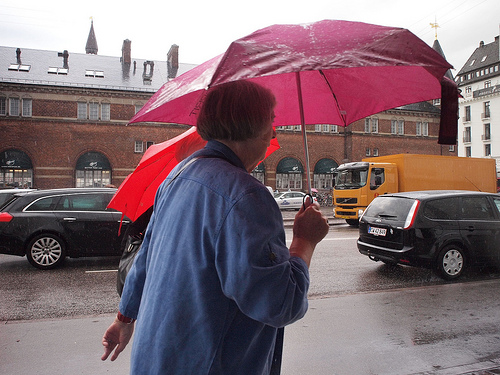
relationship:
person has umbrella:
[103, 78, 330, 374] [123, 20, 465, 127]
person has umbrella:
[115, 204, 155, 297] [104, 123, 281, 235]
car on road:
[0, 187, 144, 271] [1, 222, 497, 324]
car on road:
[357, 190, 499, 282] [1, 222, 497, 324]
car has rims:
[0, 187, 144, 271] [29, 235, 62, 266]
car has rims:
[357, 190, 499, 282] [442, 249, 465, 275]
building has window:
[454, 34, 499, 186] [465, 104, 471, 121]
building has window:
[454, 34, 499, 186] [482, 101, 490, 118]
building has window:
[454, 34, 499, 186] [482, 121, 490, 140]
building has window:
[454, 34, 499, 186] [463, 126, 473, 142]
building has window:
[454, 34, 499, 186] [465, 144, 472, 157]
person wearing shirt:
[103, 78, 330, 374] [116, 138, 310, 374]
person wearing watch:
[103, 78, 330, 374] [115, 310, 135, 326]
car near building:
[271, 188, 319, 210] [1, 44, 457, 196]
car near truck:
[357, 190, 499, 282] [330, 153, 498, 227]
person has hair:
[103, 78, 330, 374] [196, 79, 276, 141]